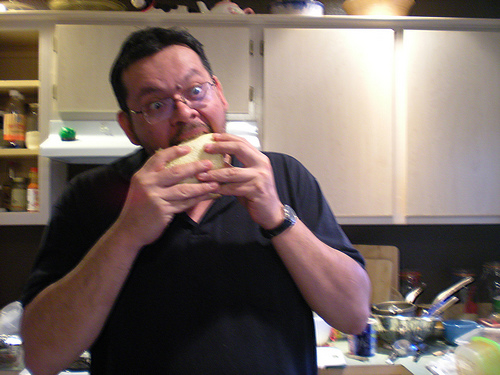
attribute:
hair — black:
[108, 26, 215, 128]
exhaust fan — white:
[40, 118, 263, 172]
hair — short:
[102, 23, 221, 110]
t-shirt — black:
[25, 126, 363, 373]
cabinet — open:
[0, 20, 51, 220]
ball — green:
[41, 116, 116, 166]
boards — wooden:
[325, 364, 413, 374]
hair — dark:
[101, 26, 221, 76]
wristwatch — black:
[257, 207, 294, 242]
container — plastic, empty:
[452, 335, 499, 374]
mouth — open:
[175, 129, 209, 144]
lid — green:
[472, 335, 499, 374]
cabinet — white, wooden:
[399, 21, 499, 223]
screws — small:
[248, 38, 254, 55]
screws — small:
[248, 85, 255, 101]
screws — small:
[259, 39, 264, 54]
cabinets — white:
[263, 37, 498, 199]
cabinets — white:
[49, 11, 253, 128]